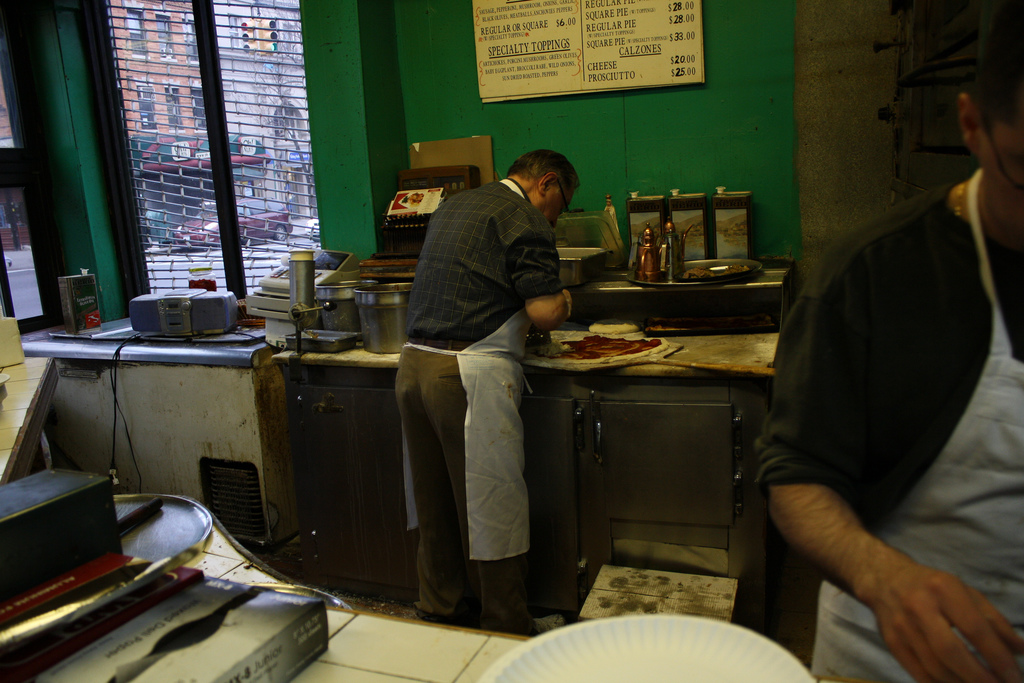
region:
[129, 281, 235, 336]
blue and gray radio on the shelf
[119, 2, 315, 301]
black window between green walls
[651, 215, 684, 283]
green bottle on top o the shelf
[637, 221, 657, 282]
red bottle on top of the shelf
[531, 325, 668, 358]
uncooked pizza on wooden pizza pallet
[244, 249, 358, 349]
big gray cash registrer on the shelf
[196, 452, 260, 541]
black air duct on white furniture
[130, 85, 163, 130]
glass window on the building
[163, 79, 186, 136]
glass window on the building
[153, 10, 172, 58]
glass window on the building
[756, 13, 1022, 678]
man wearing a white apron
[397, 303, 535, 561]
white apron man is wearing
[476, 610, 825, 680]
round white plate sitting on the counter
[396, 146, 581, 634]
man wearing brown pants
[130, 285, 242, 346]
radio sitting on the counter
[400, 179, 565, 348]
dark gray shirt man is wearing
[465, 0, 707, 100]
menu hanging on the wall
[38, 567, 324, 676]
white box holding wraping paper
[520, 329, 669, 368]
pizza sitting on the counter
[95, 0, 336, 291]
window at the back of the room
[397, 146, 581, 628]
man in black shirt and white apron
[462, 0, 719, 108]
price and menu on a green wall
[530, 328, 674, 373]
pizza on a kitchen counter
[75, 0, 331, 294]
aluminum framed window and blinds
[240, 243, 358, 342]
beige cash register on the counter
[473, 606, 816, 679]
white paper plate on the counter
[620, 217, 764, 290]
round pizza serving tray on the counter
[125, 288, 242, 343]
portable radio on the counter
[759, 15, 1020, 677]
chef in a white apron at a counter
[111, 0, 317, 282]
red car on the street outside the window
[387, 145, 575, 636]
man in glasses preparing a pizza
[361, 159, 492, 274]
old style cash register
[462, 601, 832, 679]
white paper plate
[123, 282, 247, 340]
gray boom box stereo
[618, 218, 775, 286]
silver serving platter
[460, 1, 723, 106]
menu on the wall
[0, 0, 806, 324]
wall painted green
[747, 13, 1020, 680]
man in the foreground wearing an apron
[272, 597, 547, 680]
white tiles on a counter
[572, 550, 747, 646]
dirty white tiles on the floor